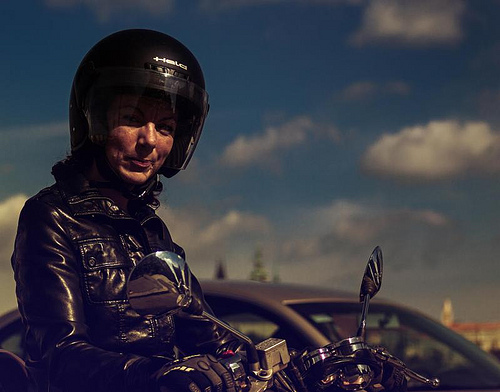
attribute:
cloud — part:
[292, 213, 327, 270]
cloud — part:
[365, 140, 412, 183]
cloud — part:
[457, 110, 498, 142]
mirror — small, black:
[119, 243, 246, 340]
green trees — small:
[215, 239, 282, 284]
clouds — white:
[341, 0, 475, 56]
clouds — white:
[357, 112, 499, 188]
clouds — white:
[209, 108, 346, 175]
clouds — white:
[154, 195, 499, 278]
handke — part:
[346, 322, 373, 367]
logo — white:
[151, 52, 189, 72]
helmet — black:
[58, 22, 217, 188]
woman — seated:
[28, 22, 276, 371]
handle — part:
[349, 293, 372, 335]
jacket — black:
[5, 177, 206, 384]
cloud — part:
[345, 109, 496, 214]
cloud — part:
[394, 143, 424, 197]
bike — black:
[146, 286, 406, 390]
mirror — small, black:
[123, 249, 195, 318]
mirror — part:
[141, 259, 225, 335]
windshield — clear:
[301, 295, 497, 377]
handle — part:
[361, 333, 408, 372]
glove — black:
[159, 349, 238, 390]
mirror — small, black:
[126, 246, 382, 316]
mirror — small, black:
[98, 252, 208, 317]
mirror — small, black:
[339, 247, 399, 313]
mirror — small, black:
[351, 236, 391, 302]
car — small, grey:
[1, 267, 498, 388]